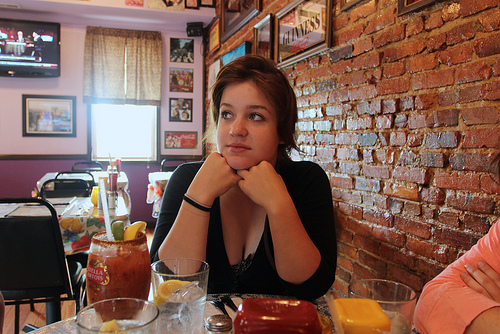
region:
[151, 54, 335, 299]
woman in a black shirt sitting a table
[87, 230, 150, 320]
bloody Mary in a beer glass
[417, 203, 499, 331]
arm of person in a peach shirt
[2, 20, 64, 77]
television on the wall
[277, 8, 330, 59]
Guinness beer sign on the brick wall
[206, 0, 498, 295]
red brick wall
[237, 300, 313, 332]
bottom of upside down ketchup bottle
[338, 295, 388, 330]
bottom of upside down mustard bottle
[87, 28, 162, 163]
window in the restaurant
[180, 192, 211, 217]
black wristband on the girl's right arm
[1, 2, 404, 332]
A woman in a restaurant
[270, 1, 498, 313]
Brown bricks on the wall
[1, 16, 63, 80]
A TV screen is turned on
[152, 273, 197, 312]
Lemon in a glass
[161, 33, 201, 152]
Photos are on the wall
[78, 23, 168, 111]
Curtains over a window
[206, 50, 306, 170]
Woman has brown hair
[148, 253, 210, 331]
A glass of ice and water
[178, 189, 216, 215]
Black bracelet around a wrist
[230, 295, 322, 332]
A red ketchup bottle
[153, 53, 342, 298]
A woman in a black blouse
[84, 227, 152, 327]
A Stella Artois glass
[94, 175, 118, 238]
A white straw in the glass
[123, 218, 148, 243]
A lemon slice on the rim of the glass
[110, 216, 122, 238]
A lime slice on the rim of the glass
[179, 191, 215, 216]
A black bracelet on the woman's arm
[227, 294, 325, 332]
The top of a ketchup bottle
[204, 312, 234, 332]
The top of a salt shaker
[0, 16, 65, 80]
A television on the wall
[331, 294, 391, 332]
The top of a mustard container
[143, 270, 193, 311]
a lemon in a glass of water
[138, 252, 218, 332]
a glass of water on the table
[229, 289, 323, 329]
part of a ketchup bottle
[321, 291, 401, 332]
part of a mustard bottle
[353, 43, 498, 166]
bricks that make up the wall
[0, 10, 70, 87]
a t.v. in the background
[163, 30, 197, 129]
a row of pictures on the wall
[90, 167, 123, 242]
a straw inside the glass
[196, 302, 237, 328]
the top of a shaker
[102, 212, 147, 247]
a lemon and lime on the side of the glass